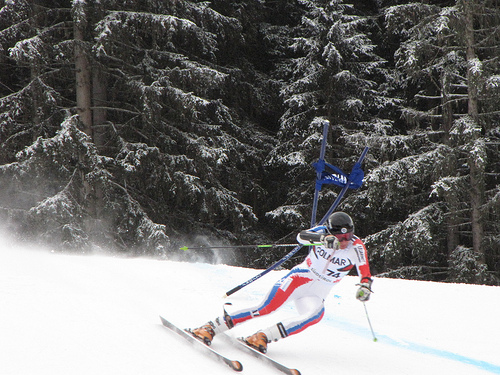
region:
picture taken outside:
[17, 30, 472, 365]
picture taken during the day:
[75, 85, 422, 362]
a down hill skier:
[116, 131, 437, 368]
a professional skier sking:
[153, 106, 433, 367]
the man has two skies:
[135, 280, 251, 372]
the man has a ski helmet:
[336, 220, 351, 225]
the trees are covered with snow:
[93, 85, 290, 173]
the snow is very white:
[48, 236, 156, 340]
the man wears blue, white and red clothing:
[201, 218, 402, 335]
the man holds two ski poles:
[183, 231, 408, 329]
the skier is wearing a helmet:
[324, 212, 355, 246]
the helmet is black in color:
[326, 212, 353, 242]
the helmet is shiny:
[326, 213, 356, 244]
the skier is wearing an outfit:
[207, 225, 372, 347]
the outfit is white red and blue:
[209, 225, 375, 350]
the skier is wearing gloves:
[356, 283, 373, 300]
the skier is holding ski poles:
[358, 294, 378, 345]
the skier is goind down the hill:
[163, 218, 386, 373]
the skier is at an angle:
[157, 210, 372, 372]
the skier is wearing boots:
[192, 315, 269, 356]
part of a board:
[258, 345, 283, 372]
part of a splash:
[96, 280, 160, 339]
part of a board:
[170, 326, 195, 355]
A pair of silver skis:
[156, 317, 302, 374]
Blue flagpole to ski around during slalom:
[307, 123, 370, 211]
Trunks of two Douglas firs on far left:
[66, 0, 116, 255]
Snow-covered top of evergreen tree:
[274, 2, 387, 114]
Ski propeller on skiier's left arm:
[356, 303, 378, 343]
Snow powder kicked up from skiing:
[1, 219, 237, 266]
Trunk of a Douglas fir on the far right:
[465, 1, 487, 283]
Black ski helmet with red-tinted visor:
[327, 210, 357, 247]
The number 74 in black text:
[325, 267, 340, 279]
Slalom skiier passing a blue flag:
[149, 207, 386, 374]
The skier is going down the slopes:
[41, 21, 446, 371]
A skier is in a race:
[55, 26, 452, 366]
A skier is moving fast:
[65, 37, 416, 372]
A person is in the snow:
[80, 11, 455, 371]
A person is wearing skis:
[85, 27, 450, 369]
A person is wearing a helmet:
[55, 51, 470, 371]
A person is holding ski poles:
[115, 56, 447, 371]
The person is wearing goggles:
[55, 45, 456, 370]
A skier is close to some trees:
[55, 10, 445, 370]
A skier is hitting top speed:
[65, 25, 430, 372]